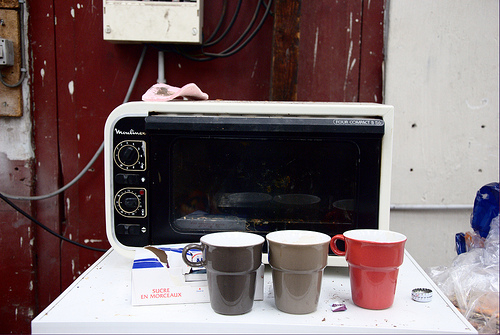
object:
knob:
[113, 139, 148, 173]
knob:
[112, 187, 147, 218]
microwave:
[101, 99, 396, 267]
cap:
[411, 287, 433, 302]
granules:
[330, 303, 347, 312]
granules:
[384, 320, 397, 328]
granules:
[322, 317, 326, 322]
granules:
[331, 280, 343, 290]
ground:
[0, 281, 500, 334]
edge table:
[317, 287, 478, 334]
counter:
[28, 246, 476, 335]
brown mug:
[183, 231, 264, 316]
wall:
[0, 0, 500, 254]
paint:
[299, 0, 385, 103]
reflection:
[178, 190, 379, 231]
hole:
[411, 123, 418, 128]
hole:
[480, 125, 486, 129]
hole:
[410, 167, 414, 172]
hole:
[478, 168, 483, 172]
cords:
[171, 0, 274, 62]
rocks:
[182, 230, 265, 316]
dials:
[110, 138, 148, 223]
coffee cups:
[264, 229, 332, 314]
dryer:
[101, 100, 395, 267]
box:
[128, 242, 266, 308]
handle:
[180, 243, 207, 269]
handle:
[330, 235, 347, 256]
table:
[31, 247, 478, 335]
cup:
[327, 228, 405, 311]